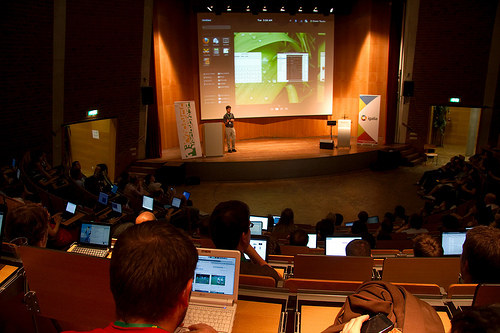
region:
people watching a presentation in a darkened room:
[0, 3, 493, 331]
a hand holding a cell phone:
[324, 307, 396, 332]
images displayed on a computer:
[169, 241, 242, 331]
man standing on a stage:
[218, 95, 250, 162]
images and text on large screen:
[196, 9, 332, 115]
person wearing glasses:
[230, 205, 258, 244]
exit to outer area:
[422, 87, 485, 164]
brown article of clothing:
[326, 276, 446, 331]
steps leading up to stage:
[373, 133, 425, 171]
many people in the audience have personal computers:
[13, 150, 194, 255]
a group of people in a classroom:
[3, 147, 499, 328]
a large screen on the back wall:
[196, 11, 341, 120]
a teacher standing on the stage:
[221, 107, 241, 154]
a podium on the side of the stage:
[199, 110, 225, 157]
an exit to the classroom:
[426, 101, 481, 158]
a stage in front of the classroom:
[151, 127, 391, 175]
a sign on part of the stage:
[171, 95, 206, 161]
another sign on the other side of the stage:
[354, 94, 380, 145]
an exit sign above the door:
[86, 107, 101, 122]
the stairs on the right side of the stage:
[386, 137, 423, 167]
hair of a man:
[113, 246, 177, 310]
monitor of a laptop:
[204, 259, 231, 292]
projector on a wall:
[199, 5, 320, 104]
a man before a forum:
[214, 103, 239, 150]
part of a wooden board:
[299, 255, 370, 279]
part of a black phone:
[369, 309, 389, 329]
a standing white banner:
[165, 102, 204, 165]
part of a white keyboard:
[211, 310, 236, 327]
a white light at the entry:
[448, 91, 462, 108]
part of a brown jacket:
[390, 287, 427, 321]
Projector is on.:
[191, 14, 341, 114]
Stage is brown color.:
[173, 58, 386, 150]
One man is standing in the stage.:
[177, 76, 392, 156]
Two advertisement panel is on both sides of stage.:
[173, 101, 383, 160]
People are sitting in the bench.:
[15, 185, 472, 321]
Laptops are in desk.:
[43, 185, 461, 332]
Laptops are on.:
[7, 185, 467, 286]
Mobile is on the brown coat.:
[330, 300, 416, 330]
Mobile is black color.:
[355, 310, 392, 330]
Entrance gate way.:
[422, 93, 489, 168]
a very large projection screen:
[178, 0, 360, 133]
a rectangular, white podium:
[195, 110, 245, 168]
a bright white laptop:
[127, 230, 261, 332]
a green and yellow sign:
[165, 86, 220, 175]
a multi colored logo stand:
[349, 77, 406, 171]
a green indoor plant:
[427, 97, 457, 152]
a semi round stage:
[131, 134, 434, 182]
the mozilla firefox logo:
[198, 33, 218, 52]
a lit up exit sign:
[82, 107, 105, 123]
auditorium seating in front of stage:
[11, 121, 498, 329]